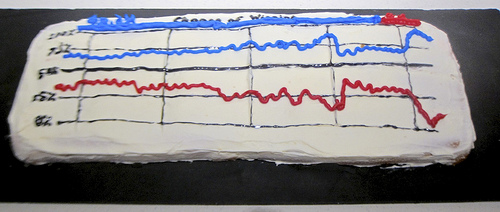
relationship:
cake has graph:
[7, 12, 477, 168] [32, 16, 444, 133]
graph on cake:
[32, 16, 444, 133] [7, 12, 477, 168]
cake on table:
[7, 12, 477, 168] [1, 9, 500, 202]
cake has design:
[7, 12, 477, 168] [32, 16, 444, 133]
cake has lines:
[7, 12, 477, 168] [56, 19, 445, 131]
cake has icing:
[7, 12, 477, 168] [11, 12, 476, 166]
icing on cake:
[11, 12, 476, 166] [7, 12, 477, 168]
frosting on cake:
[11, 12, 476, 166] [7, 12, 477, 168]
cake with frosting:
[7, 12, 477, 168] [11, 12, 476, 166]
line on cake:
[51, 77, 445, 129] [10, 24, 477, 161]